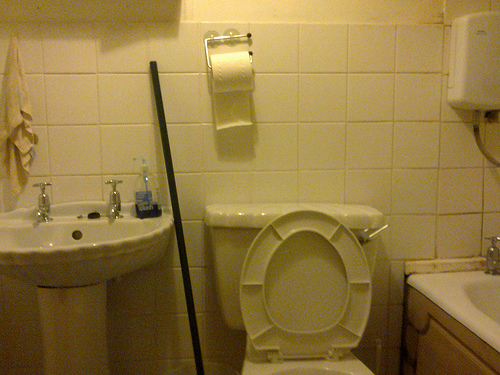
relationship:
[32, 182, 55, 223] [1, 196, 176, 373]
faucet on sink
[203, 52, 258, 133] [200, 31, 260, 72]
toilet paper on roll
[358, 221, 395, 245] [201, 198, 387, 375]
lever on toilet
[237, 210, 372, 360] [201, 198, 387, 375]
lid on toilet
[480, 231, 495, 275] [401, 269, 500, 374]
faucet on bathtub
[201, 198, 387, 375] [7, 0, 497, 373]
toilet inside bathroom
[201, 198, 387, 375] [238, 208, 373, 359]
toilet has seat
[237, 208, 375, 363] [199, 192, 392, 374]
lid on toilet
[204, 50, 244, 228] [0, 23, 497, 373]
roll on wall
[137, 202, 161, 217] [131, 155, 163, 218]
soap in bottle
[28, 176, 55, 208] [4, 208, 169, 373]
knob on sink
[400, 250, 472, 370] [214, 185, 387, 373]
bathtub by toilet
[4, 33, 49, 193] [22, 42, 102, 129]
towel on wall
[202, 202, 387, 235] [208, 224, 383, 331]
top on tank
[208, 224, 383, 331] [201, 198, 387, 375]
tank on toilet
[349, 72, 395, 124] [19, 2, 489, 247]
tile on wall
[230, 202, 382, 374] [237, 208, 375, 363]
toilet with lid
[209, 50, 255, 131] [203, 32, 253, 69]
toilet paper on paper holder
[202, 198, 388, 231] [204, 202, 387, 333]
lid on tank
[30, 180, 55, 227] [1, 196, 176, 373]
faucet on sink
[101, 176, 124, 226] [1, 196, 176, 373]
faucet on sink